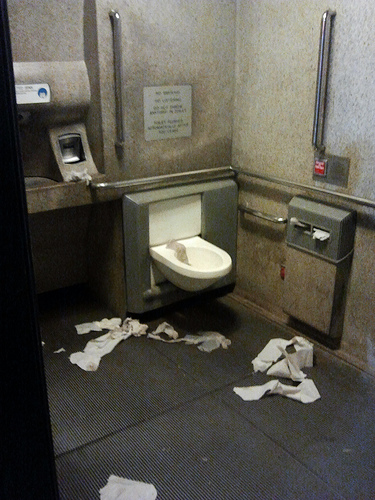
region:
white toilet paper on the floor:
[35, 311, 324, 498]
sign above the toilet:
[139, 80, 199, 142]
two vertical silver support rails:
[101, 3, 339, 152]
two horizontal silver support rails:
[77, 160, 373, 262]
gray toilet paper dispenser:
[284, 193, 355, 259]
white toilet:
[142, 193, 234, 299]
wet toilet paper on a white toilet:
[162, 237, 193, 268]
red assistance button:
[309, 156, 328, 179]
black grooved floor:
[42, 281, 374, 497]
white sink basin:
[19, 175, 64, 188]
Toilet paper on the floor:
[74, 314, 318, 403]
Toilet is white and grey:
[129, 195, 232, 308]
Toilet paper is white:
[72, 312, 317, 419]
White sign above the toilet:
[139, 85, 199, 143]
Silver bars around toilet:
[97, 8, 372, 228]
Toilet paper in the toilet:
[161, 227, 222, 282]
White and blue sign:
[15, 82, 51, 104]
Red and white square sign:
[311, 158, 328, 177]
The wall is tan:
[7, 0, 367, 350]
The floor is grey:
[42, 312, 372, 492]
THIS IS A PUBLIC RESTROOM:
[47, 121, 347, 351]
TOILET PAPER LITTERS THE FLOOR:
[60, 312, 341, 471]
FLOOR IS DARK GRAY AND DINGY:
[51, 370, 327, 491]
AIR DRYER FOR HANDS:
[11, 72, 47, 154]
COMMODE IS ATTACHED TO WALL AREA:
[115, 180, 269, 323]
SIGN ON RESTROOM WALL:
[122, 65, 242, 156]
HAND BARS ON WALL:
[79, 144, 359, 223]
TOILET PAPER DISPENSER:
[285, 185, 358, 269]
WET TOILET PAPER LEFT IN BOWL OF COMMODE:
[152, 227, 218, 281]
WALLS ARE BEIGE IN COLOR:
[19, 9, 336, 173]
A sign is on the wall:
[133, 76, 218, 177]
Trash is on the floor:
[76, 348, 304, 469]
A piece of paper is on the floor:
[80, 464, 174, 497]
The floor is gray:
[98, 377, 245, 441]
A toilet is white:
[156, 228, 282, 294]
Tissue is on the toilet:
[152, 219, 217, 281]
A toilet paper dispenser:
[261, 188, 367, 281]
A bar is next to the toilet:
[226, 183, 310, 248]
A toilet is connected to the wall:
[108, 176, 297, 281]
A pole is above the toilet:
[81, 11, 191, 157]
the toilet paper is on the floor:
[238, 333, 327, 412]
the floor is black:
[162, 422, 214, 490]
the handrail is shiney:
[239, 200, 289, 231]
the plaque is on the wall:
[139, 79, 199, 152]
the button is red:
[305, 150, 334, 185]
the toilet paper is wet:
[160, 239, 187, 254]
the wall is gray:
[241, 15, 277, 92]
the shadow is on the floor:
[175, 312, 245, 335]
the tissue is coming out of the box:
[281, 203, 353, 258]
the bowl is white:
[161, 234, 230, 295]